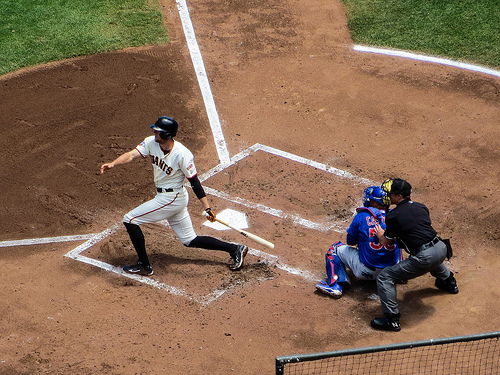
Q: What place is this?
A: It is a field.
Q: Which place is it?
A: It is a field.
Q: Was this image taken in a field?
A: Yes, it was taken in a field.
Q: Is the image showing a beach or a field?
A: It is showing a field.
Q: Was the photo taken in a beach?
A: No, the picture was taken in a field.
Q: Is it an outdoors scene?
A: Yes, it is outdoors.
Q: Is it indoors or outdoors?
A: It is outdoors.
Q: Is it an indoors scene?
A: No, it is outdoors.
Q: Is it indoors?
A: No, it is outdoors.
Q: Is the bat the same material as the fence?
A: No, the bat is made of wood and the fence is made of metal.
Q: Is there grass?
A: Yes, there is grass.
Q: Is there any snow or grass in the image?
A: Yes, there is grass.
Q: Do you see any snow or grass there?
A: Yes, there is grass.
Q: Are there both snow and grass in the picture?
A: No, there is grass but no snow.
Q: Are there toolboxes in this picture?
A: No, there are no toolboxes.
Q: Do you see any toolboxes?
A: No, there are no toolboxes.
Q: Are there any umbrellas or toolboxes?
A: No, there are no toolboxes or umbrellas.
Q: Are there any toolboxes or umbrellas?
A: No, there are no toolboxes or umbrellas.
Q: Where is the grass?
A: The grass is on the field.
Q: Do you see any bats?
A: Yes, there is a bat.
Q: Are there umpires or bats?
A: Yes, there is a bat.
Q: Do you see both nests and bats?
A: No, there is a bat but no nests.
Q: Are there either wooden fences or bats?
A: Yes, there is a wood bat.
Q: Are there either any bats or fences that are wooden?
A: Yes, the bat is wooden.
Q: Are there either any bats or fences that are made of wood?
A: Yes, the bat is made of wood.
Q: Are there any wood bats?
A: Yes, there is a wood bat.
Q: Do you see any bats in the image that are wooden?
A: Yes, there is a bat that is wooden.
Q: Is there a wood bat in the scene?
A: Yes, there is a bat that is made of wood.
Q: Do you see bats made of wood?
A: Yes, there is a bat that is made of wood.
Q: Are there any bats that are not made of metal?
A: Yes, there is a bat that is made of wood.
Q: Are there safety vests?
A: No, there are no safety vests.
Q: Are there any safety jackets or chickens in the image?
A: No, there are no safety jackets or chickens.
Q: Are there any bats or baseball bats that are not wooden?
A: No, there is a bat but it is wooden.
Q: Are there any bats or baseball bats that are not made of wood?
A: No, there is a bat but it is made of wood.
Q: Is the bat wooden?
A: Yes, the bat is wooden.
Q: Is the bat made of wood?
A: Yes, the bat is made of wood.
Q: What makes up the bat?
A: The bat is made of wood.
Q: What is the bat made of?
A: The bat is made of wood.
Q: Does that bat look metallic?
A: No, the bat is wooden.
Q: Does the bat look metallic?
A: No, the bat is wooden.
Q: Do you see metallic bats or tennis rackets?
A: No, there is a bat but it is wooden.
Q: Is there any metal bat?
A: No, there is a bat but it is made of wood.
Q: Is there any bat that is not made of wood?
A: No, there is a bat but it is made of wood.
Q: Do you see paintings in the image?
A: No, there are no paintings.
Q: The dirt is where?
A: The dirt is on the field.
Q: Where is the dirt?
A: The dirt is on the field.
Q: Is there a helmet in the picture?
A: Yes, there is a helmet.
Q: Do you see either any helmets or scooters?
A: Yes, there is a helmet.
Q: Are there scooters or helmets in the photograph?
A: Yes, there is a helmet.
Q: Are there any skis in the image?
A: No, there are no skis.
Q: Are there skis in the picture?
A: No, there are no skis.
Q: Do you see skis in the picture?
A: No, there are no skis.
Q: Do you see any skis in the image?
A: No, there are no skis.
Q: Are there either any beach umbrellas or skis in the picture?
A: No, there are no skis or beach umbrellas.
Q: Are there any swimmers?
A: No, there are no swimmers.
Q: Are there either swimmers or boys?
A: No, there are no swimmers or boys.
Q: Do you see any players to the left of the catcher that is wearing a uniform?
A: Yes, there is a player to the left of the catcher.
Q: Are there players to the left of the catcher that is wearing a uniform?
A: Yes, there is a player to the left of the catcher.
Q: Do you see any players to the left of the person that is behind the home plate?
A: Yes, there is a player to the left of the catcher.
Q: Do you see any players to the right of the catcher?
A: No, the player is to the left of the catcher.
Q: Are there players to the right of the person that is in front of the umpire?
A: No, the player is to the left of the catcher.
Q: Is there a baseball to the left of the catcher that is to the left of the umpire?
A: No, there is a player to the left of the catcher.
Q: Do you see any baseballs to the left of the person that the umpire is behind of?
A: No, there is a player to the left of the catcher.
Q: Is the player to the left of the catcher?
A: Yes, the player is to the left of the catcher.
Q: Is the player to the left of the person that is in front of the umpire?
A: Yes, the player is to the left of the catcher.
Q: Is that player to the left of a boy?
A: No, the player is to the left of the catcher.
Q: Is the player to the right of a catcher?
A: No, the player is to the left of a catcher.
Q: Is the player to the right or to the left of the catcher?
A: The player is to the left of the catcher.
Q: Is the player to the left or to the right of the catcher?
A: The player is to the left of the catcher.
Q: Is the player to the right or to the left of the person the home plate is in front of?
A: The player is to the left of the catcher.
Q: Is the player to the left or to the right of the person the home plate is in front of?
A: The player is to the left of the catcher.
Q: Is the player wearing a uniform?
A: Yes, the player is wearing a uniform.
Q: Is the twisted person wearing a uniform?
A: Yes, the player is wearing a uniform.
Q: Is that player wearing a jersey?
A: No, the player is wearing a uniform.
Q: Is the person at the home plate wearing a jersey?
A: No, the player is wearing a uniform.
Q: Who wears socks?
A: The player wears socks.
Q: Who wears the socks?
A: The player wears socks.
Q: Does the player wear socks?
A: Yes, the player wears socks.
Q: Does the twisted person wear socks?
A: Yes, the player wears socks.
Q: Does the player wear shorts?
A: No, the player wears socks.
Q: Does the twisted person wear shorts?
A: No, the player wears socks.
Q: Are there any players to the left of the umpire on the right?
A: Yes, there is a player to the left of the umpire.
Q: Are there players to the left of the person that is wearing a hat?
A: Yes, there is a player to the left of the umpire.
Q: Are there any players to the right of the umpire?
A: No, the player is to the left of the umpire.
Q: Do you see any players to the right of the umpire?
A: No, the player is to the left of the umpire.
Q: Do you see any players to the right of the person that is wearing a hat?
A: No, the player is to the left of the umpire.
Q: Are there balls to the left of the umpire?
A: No, there is a player to the left of the umpire.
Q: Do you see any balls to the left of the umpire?
A: No, there is a player to the left of the umpire.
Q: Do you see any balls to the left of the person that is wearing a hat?
A: No, there is a player to the left of the umpire.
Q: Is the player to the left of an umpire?
A: Yes, the player is to the left of an umpire.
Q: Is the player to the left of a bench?
A: No, the player is to the left of an umpire.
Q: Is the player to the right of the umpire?
A: No, the player is to the left of the umpire.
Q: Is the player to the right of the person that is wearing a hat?
A: No, the player is to the left of the umpire.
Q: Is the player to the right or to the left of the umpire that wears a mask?
A: The player is to the left of the umpire.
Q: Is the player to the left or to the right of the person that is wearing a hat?
A: The player is to the left of the umpire.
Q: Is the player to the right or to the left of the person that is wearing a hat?
A: The player is to the left of the umpire.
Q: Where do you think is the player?
A: The player is at the home plate.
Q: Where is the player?
A: The player is at the home plate.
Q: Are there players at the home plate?
A: Yes, there is a player at the home plate.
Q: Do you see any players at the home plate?
A: Yes, there is a player at the home plate.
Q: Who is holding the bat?
A: The player is holding the bat.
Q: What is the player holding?
A: The player is holding the bat.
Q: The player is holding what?
A: The player is holding the bat.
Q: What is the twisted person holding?
A: The player is holding the bat.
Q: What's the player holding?
A: The player is holding the bat.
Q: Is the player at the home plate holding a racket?
A: No, the player is holding the bat.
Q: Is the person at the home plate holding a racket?
A: No, the player is holding the bat.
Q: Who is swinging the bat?
A: The player is swinging the bat.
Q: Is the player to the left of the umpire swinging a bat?
A: Yes, the player is swinging a bat.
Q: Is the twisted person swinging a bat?
A: Yes, the player is swinging a bat.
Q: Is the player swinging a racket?
A: No, the player is swinging a bat.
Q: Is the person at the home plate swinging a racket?
A: No, the player is swinging a bat.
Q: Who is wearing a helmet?
A: The player is wearing a helmet.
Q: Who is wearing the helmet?
A: The player is wearing a helmet.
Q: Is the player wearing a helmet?
A: Yes, the player is wearing a helmet.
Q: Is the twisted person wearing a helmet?
A: Yes, the player is wearing a helmet.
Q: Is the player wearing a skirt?
A: No, the player is wearing a helmet.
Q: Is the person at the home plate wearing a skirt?
A: No, the player is wearing a helmet.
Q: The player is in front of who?
A: The player is in front of the catcher.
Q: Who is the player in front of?
A: The player is in front of the catcher.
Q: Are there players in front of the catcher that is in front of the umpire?
A: Yes, there is a player in front of the catcher.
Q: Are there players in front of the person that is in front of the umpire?
A: Yes, there is a player in front of the catcher.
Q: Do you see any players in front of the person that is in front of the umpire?
A: Yes, there is a player in front of the catcher.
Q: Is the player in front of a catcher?
A: Yes, the player is in front of a catcher.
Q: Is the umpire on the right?
A: Yes, the umpire is on the right of the image.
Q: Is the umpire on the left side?
A: No, the umpire is on the right of the image.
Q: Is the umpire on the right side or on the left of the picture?
A: The umpire is on the right of the image.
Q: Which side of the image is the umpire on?
A: The umpire is on the right of the image.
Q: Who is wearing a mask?
A: The umpire is wearing a mask.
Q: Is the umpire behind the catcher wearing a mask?
A: Yes, the umpire is wearing a mask.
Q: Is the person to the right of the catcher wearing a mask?
A: Yes, the umpire is wearing a mask.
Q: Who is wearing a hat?
A: The umpire is wearing a hat.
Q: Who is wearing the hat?
A: The umpire is wearing a hat.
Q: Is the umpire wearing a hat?
A: Yes, the umpire is wearing a hat.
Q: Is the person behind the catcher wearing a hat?
A: Yes, the umpire is wearing a hat.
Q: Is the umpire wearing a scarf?
A: No, the umpire is wearing a hat.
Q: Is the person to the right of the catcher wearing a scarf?
A: No, the umpire is wearing a hat.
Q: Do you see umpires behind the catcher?
A: Yes, there is an umpire behind the catcher.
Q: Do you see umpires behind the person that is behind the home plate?
A: Yes, there is an umpire behind the catcher.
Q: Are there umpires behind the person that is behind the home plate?
A: Yes, there is an umpire behind the catcher.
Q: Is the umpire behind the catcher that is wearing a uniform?
A: Yes, the umpire is behind the catcher.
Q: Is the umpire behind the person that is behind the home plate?
A: Yes, the umpire is behind the catcher.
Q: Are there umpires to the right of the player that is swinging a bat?
A: Yes, there is an umpire to the right of the player.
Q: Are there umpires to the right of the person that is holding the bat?
A: Yes, there is an umpire to the right of the player.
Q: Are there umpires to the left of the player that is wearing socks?
A: No, the umpire is to the right of the player.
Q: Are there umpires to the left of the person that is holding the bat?
A: No, the umpire is to the right of the player.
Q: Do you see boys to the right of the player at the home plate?
A: No, there is an umpire to the right of the player.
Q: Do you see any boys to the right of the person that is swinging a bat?
A: No, there is an umpire to the right of the player.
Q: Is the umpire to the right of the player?
A: Yes, the umpire is to the right of the player.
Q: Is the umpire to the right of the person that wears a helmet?
A: Yes, the umpire is to the right of the player.